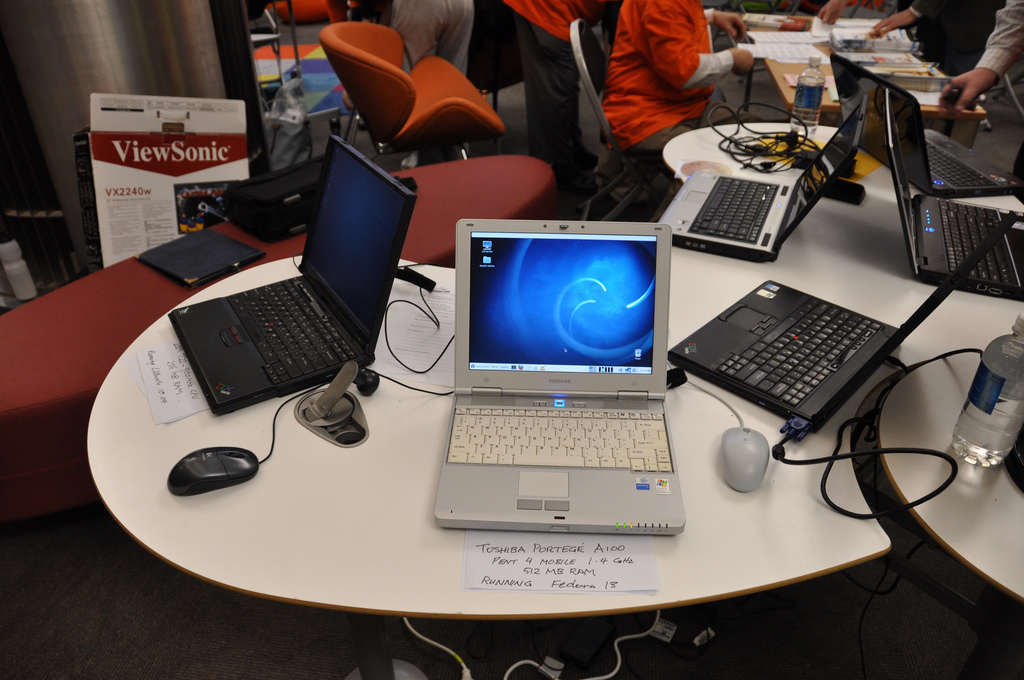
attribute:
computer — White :
[427, 209, 683, 536]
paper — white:
[462, 523, 674, 608]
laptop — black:
[164, 122, 443, 427]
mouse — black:
[159, 439, 266, 500]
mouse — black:
[111, 433, 248, 488]